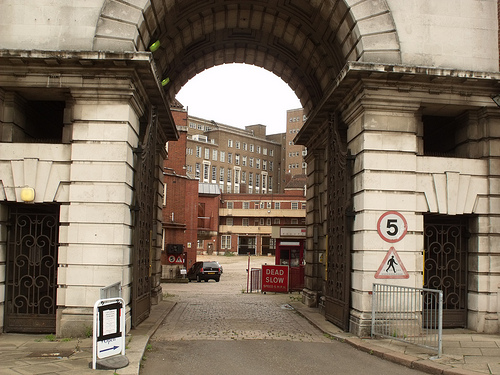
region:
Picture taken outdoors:
[12, 8, 469, 361]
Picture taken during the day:
[64, 58, 487, 275]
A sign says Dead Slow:
[259, 261, 289, 292]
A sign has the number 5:
[380, 213, 403, 238]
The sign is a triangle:
[369, 248, 411, 280]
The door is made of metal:
[19, 235, 64, 362]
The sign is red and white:
[261, 264, 289, 287]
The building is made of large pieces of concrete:
[86, 144, 121, 274]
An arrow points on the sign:
[101, 346, 123, 353]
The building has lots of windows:
[183, 113, 275, 185]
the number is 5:
[371, 203, 425, 260]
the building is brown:
[203, 128, 281, 195]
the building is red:
[189, 192, 292, 244]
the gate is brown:
[119, 120, 171, 326]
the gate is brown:
[305, 120, 350, 320]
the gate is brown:
[415, 209, 466, 372]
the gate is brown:
[6, 203, 80, 330]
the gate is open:
[120, 85, 387, 347]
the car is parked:
[171, 253, 243, 308]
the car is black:
[186, 255, 249, 300]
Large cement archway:
[13, 2, 493, 362]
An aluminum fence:
[371, 283, 451, 356]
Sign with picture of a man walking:
[371, 243, 411, 276]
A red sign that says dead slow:
[255, 261, 295, 295]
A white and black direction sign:
[91, 299, 128, 369]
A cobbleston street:
[164, 282, 309, 348]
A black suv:
[188, 253, 226, 287]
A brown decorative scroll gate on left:
[6, 210, 61, 326]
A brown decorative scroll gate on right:
[426, 218, 471, 330]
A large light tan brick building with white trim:
[192, 107, 307, 190]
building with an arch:
[79, 1, 426, 371]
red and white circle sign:
[375, 210, 410, 243]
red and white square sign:
[257, 260, 291, 298]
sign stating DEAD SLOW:
[261, 260, 296, 297]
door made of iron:
[5, 202, 60, 338]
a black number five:
[380, 208, 401, 241]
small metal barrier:
[365, 275, 455, 361]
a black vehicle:
[188, 258, 224, 283]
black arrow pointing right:
[97, 340, 124, 355]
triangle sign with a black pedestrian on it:
[368, 243, 413, 282]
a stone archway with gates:
[84, 5, 416, 336]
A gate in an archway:
[320, 99, 357, 329]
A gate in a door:
[419, 209, 470, 320]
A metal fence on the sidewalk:
[368, 274, 448, 348]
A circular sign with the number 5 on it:
[376, 208, 406, 238]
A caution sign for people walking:
[375, 242, 406, 279]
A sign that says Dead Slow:
[255, 266, 290, 287]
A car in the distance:
[185, 256, 222, 280]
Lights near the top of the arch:
[145, 35, 172, 93]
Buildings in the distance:
[178, 83, 310, 283]